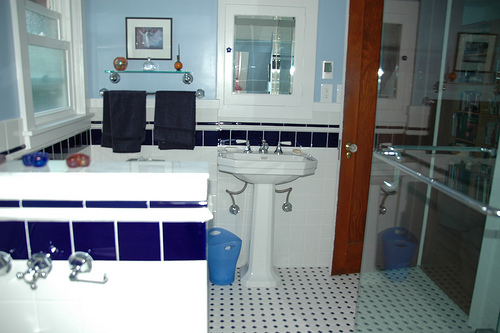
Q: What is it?
A: Bathroom.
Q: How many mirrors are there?
A: One.